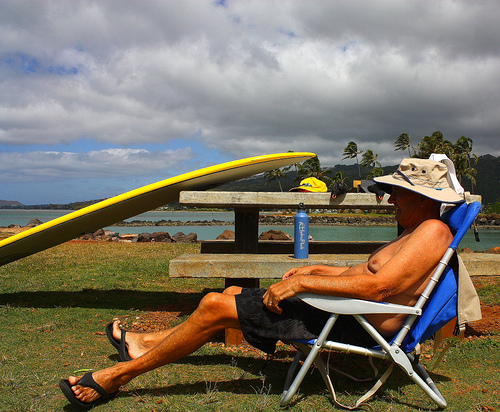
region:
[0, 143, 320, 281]
Long yellow surfboard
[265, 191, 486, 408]
Lawn chair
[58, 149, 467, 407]
Man relaxing in a lawn chair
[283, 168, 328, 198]
Yellow baseball cap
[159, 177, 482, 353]
Stone picnic table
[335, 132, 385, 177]
Green palm trees on the other side of the river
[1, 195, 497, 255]
River in the background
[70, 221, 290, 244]
Rocks on the river bank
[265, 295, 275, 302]
The man's wedding ring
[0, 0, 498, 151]
Gray clouds in the sky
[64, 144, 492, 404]
a man sitting in a lawn chair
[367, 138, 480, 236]
a man with a hat on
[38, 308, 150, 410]
a man wearing flip flops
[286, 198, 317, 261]
a blue and white water bottle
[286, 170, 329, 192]
a yellow and blue cap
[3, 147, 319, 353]
a yellow surfboard sitting on a picnic table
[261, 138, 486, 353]
a man not wearing a shirt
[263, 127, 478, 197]
several palm trees blowing in the wind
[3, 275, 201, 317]
the shadow of a surf board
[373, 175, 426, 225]
a man smiling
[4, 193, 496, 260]
Beach front with rock pier.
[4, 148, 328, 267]
Yellow surf board with orange marking.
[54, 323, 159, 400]
Black flip flops for protection.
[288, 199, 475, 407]
Sun chair with blue lining.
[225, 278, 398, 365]
Black cotton shorts for summer weather.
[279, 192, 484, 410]
Gray metal for support on chair.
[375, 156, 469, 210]
Tan hat to keep out the UV rays.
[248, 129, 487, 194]
Green palm trees blowing in the wind.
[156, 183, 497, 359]
Gray cement picnic table with bench.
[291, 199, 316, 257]
Blue water bottle with black cap.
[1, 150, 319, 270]
yellow surf board leaning on table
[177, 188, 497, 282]
metal table by man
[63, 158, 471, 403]
man in chair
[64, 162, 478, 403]
man without shirt in chair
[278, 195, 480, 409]
blue chair by table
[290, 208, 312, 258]
blue bottle on table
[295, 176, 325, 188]
yellow hat on table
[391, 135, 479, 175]
trees blowing in wind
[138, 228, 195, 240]
rocks by water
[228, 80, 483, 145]
dark clouds in sky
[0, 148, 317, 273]
The surfboard is yellow.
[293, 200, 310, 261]
The water bottle is blue.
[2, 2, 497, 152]
The sky is cloudy.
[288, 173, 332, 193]
The hat is yellow.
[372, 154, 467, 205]
The hat is beige.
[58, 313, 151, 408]
The man wears black sandals.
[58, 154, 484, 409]
The man is sitting in a chair.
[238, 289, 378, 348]
The man wears black shorts.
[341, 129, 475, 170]
The palm trees are being blown by wind.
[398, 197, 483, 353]
The chair is blue and gray.